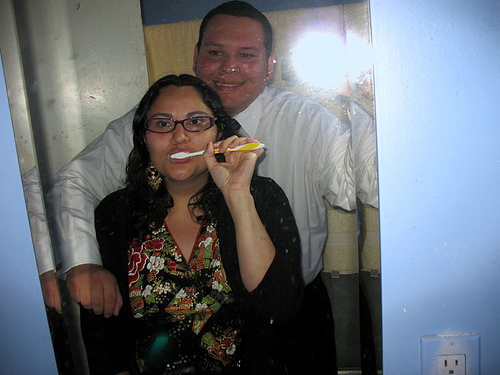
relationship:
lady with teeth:
[64, 87, 276, 373] [161, 131, 200, 157]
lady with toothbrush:
[64, 87, 276, 373] [143, 122, 254, 161]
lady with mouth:
[64, 87, 276, 373] [149, 133, 219, 193]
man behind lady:
[207, 33, 355, 229] [85, 84, 265, 296]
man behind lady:
[207, 33, 355, 229] [102, 71, 377, 371]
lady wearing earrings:
[64, 87, 276, 373] [144, 165, 159, 186]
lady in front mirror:
[64, 87, 276, 373] [6, 2, 383, 372]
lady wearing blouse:
[64, 87, 276, 373] [121, 210, 251, 371]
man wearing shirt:
[51, 9, 384, 371] [44, 84, 356, 281]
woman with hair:
[37, 67, 314, 362] [124, 82, 251, 224]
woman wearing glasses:
[37, 67, 314, 362] [135, 109, 219, 138]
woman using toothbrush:
[37, 67, 314, 362] [169, 136, 269, 159]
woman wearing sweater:
[37, 67, 314, 362] [60, 178, 325, 364]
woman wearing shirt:
[37, 67, 314, 362] [117, 218, 239, 361]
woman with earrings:
[37, 67, 314, 362] [144, 165, 159, 186]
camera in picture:
[69, 8, 359, 348] [0, 6, 484, 368]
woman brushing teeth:
[37, 67, 314, 362] [163, 151, 197, 163]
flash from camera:
[288, 19, 367, 106] [263, 10, 377, 125]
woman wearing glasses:
[37, 67, 314, 362] [148, 110, 217, 136]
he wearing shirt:
[46, 3, 391, 372] [56, 80, 370, 272]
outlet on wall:
[425, 337, 475, 369] [382, 58, 484, 360]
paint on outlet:
[437, 324, 466, 347] [424, 335, 475, 366]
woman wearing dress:
[37, 67, 314, 362] [109, 216, 284, 373]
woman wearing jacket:
[37, 67, 314, 362] [91, 164, 307, 364]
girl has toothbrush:
[83, 67, 313, 372] [168, 140, 276, 164]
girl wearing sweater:
[83, 67, 313, 372] [97, 179, 304, 360]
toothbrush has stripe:
[166, 134, 265, 156] [224, 140, 264, 153]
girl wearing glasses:
[83, 67, 313, 372] [147, 108, 218, 139]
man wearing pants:
[51, 9, 384, 371] [288, 278, 353, 370]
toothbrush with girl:
[166, 134, 265, 156] [83, 67, 313, 372]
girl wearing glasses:
[83, 67, 313, 372] [146, 111, 220, 131]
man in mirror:
[51, 9, 384, 371] [6, 2, 383, 372]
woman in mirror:
[37, 67, 314, 362] [6, 2, 383, 372]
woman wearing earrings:
[37, 67, 314, 362] [140, 160, 164, 190]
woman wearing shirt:
[37, 67, 314, 362] [118, 213, 249, 357]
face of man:
[193, 19, 266, 111] [55, 1, 350, 353]